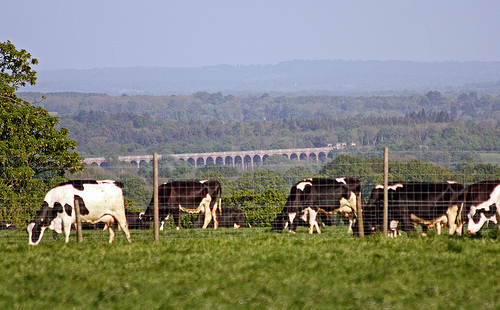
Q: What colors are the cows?
A: Black, white.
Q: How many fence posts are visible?
A: Two.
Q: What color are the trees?
A: Green.